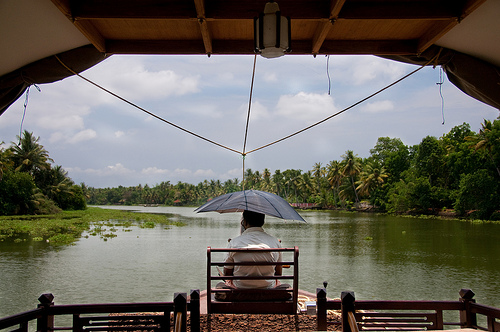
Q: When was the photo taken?
A: Daytime.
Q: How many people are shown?
A: One.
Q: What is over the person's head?
A: Umbrella.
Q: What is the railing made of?
A: Wood.